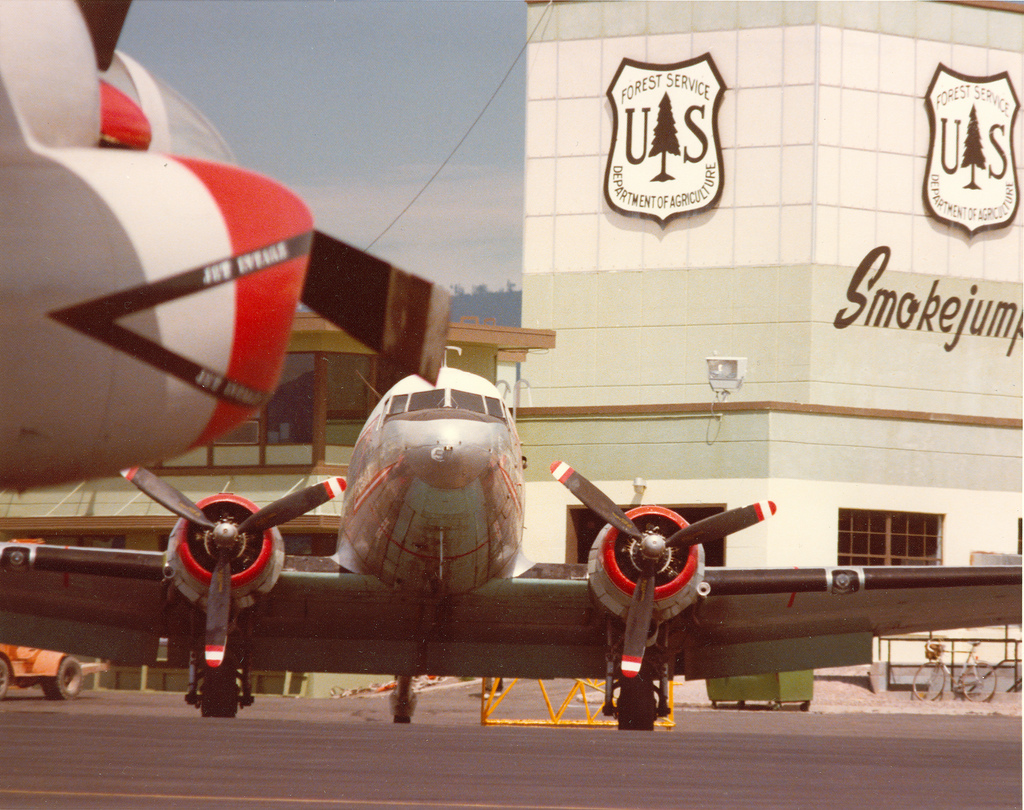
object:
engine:
[547, 452, 775, 681]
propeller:
[553, 456, 783, 690]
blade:
[197, 555, 232, 673]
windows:
[373, 383, 512, 427]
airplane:
[0, 346, 1024, 739]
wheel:
[176, 662, 256, 728]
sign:
[599, 49, 730, 235]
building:
[517, 5, 993, 717]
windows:
[827, 508, 953, 572]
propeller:
[618, 579, 670, 681]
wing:
[512, 565, 1024, 683]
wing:
[2, 532, 352, 684]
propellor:
[121, 452, 349, 675]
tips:
[545, 457, 573, 494]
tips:
[751, 491, 778, 523]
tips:
[611, 654, 646, 681]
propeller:
[109, 454, 210, 530]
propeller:
[195, 545, 230, 670]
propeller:
[545, 449, 652, 547]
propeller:
[668, 496, 783, 546]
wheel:
[598, 667, 674, 733]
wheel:
[33, 655, 91, 701]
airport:
[514, 0, 1021, 683]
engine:
[537, 456, 773, 682]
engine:
[113, 459, 345, 675]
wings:
[0, 512, 1022, 688]